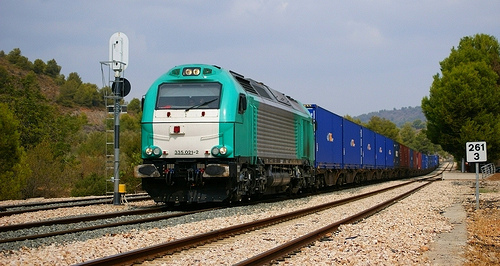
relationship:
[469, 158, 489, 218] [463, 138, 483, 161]
pole supporting sign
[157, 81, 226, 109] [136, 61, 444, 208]
windshield on train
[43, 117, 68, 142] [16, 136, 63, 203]
leaves on tree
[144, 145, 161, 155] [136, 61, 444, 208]
headlight on train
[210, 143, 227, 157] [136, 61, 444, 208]
headlight on train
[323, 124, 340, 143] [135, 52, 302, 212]
logo on train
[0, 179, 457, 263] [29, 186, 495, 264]
gravel near tracks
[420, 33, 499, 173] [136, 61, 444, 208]
tree behind train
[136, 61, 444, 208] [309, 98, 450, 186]
train hauls freight cars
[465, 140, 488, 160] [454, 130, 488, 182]
261 3 on sign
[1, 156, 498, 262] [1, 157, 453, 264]
gravel around tracks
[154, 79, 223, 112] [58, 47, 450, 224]
window on train.